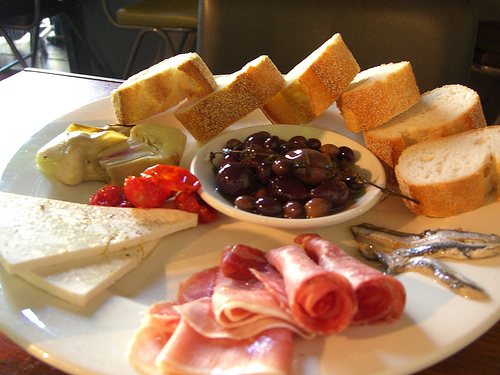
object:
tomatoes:
[90, 183, 122, 207]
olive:
[287, 201, 302, 217]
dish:
[190, 124, 385, 227]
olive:
[304, 197, 331, 216]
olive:
[217, 165, 251, 194]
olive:
[319, 144, 340, 156]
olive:
[290, 137, 308, 145]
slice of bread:
[110, 52, 219, 126]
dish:
[1, 75, 499, 373]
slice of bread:
[174, 56, 288, 142]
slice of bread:
[260, 33, 361, 125]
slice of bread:
[337, 61, 422, 132]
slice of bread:
[363, 84, 487, 185]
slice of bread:
[394, 126, 499, 219]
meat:
[292, 232, 407, 325]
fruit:
[124, 174, 172, 209]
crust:
[176, 56, 285, 140]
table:
[1, 67, 499, 374]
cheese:
[0, 189, 199, 273]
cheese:
[15, 234, 164, 306]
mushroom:
[98, 124, 186, 186]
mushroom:
[36, 124, 137, 186]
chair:
[104, 0, 199, 80]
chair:
[0, 1, 58, 70]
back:
[102, 0, 120, 26]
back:
[34, 0, 52, 28]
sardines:
[348, 220, 499, 302]